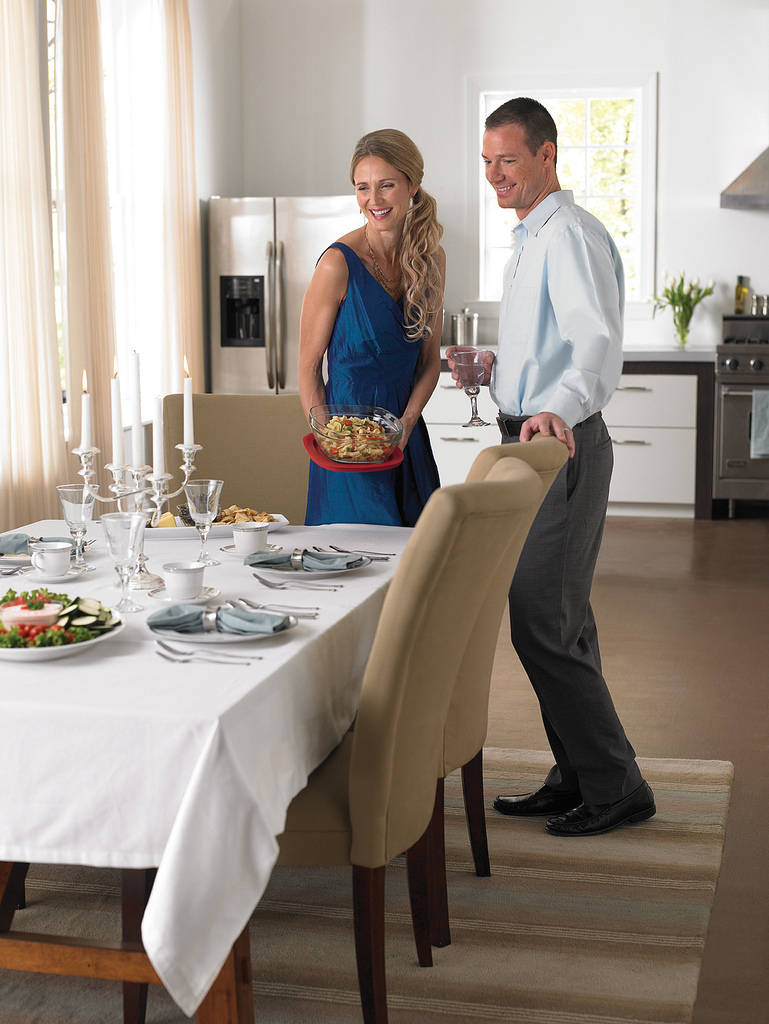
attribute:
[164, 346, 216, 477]
candle — displayed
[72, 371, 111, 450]
candle — displayed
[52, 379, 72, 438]
candle — displayed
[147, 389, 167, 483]
candle — displayed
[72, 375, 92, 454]
candle — displayed